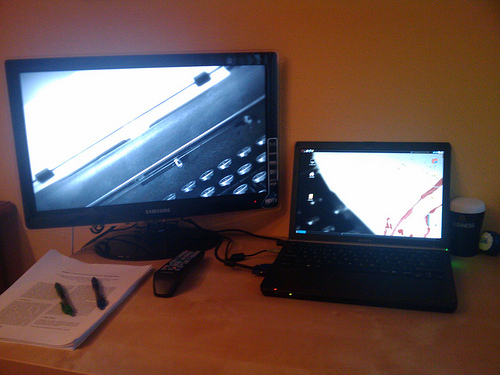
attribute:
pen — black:
[90, 275, 107, 310]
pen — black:
[53, 280, 73, 315]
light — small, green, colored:
[440, 240, 450, 250]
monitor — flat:
[6, 44, 288, 261]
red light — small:
[250, 196, 260, 208]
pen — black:
[88, 275, 108, 315]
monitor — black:
[21, 50, 306, 252]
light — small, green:
[441, 242, 451, 255]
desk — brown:
[1, 227, 497, 374]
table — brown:
[92, 283, 366, 357]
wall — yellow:
[3, 0, 497, 197]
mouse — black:
[146, 241, 211, 302]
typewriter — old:
[308, 157, 440, 244]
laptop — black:
[244, 110, 474, 330]